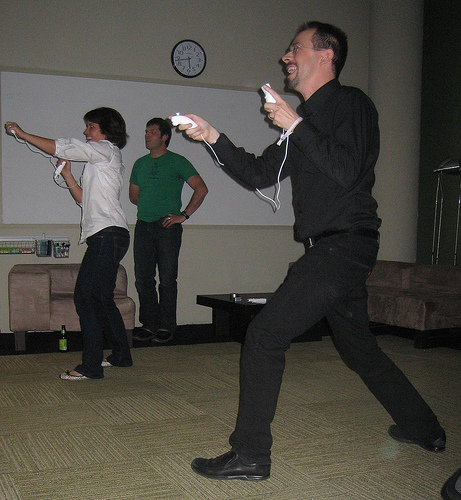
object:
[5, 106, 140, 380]
female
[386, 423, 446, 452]
dark shoe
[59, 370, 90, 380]
flipflop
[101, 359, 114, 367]
flipflop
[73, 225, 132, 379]
jeans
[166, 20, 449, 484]
man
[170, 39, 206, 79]
clock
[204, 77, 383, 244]
shirt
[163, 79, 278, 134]
wii game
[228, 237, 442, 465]
pants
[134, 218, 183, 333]
pants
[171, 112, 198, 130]
game controller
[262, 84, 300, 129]
hand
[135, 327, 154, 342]
shoe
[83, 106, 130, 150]
dark hair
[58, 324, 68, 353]
bottle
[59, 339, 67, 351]
label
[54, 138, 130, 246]
blouse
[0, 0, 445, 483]
play games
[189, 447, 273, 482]
shoe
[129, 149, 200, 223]
shirt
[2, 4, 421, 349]
wall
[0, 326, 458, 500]
floor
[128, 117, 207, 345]
guy